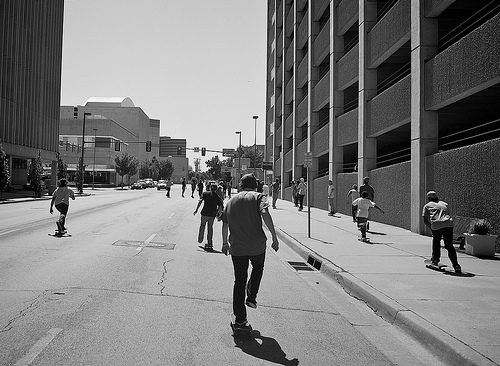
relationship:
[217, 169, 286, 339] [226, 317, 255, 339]
man on skateboard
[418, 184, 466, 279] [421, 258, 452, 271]
man on skateboard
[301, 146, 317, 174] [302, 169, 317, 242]
sign on pole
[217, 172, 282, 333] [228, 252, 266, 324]
man wearing pants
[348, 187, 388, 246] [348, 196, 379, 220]
boy wearing shirt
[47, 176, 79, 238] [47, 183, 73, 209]
person wearing shirt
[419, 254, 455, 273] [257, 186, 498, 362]
skateboard on sidewalk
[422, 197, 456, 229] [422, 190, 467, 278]
shirt on man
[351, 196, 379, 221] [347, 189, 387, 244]
shirt on boy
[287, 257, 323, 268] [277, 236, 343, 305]
drains in ditch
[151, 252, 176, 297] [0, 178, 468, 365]
crack in road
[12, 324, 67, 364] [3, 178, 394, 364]
paint on road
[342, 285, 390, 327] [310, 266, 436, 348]
crack on curb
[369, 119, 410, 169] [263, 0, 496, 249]
window on building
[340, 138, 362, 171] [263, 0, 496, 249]
window on building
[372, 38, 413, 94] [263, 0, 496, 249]
window on building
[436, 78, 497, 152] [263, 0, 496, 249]
window on building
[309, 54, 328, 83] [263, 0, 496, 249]
window on building